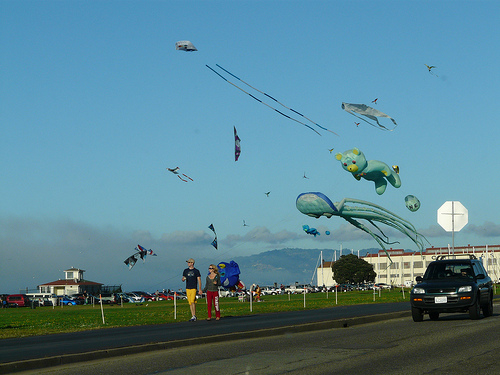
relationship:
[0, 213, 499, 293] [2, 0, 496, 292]
clouds in sky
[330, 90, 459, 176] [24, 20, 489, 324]
kite in sky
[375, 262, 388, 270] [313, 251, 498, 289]
window on building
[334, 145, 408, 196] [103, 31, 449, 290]
kite in sky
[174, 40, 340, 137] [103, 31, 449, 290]
kite in sky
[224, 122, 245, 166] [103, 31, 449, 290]
kite in sky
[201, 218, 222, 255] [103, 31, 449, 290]
kite in sky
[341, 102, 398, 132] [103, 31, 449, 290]
kite in sky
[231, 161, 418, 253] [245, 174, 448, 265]
kite in air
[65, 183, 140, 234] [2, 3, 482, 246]
clouds in sky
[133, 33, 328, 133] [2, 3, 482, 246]
kite in sky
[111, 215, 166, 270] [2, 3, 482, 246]
kite in sky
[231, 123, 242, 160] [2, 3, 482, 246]
kite in sky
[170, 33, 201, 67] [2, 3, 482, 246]
kite in sky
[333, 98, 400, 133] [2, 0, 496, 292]
kite in sky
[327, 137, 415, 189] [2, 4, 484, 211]
kite in sky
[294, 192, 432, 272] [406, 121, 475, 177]
kite in sky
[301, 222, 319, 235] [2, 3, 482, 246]
kite in sky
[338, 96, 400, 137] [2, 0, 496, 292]
kite in sky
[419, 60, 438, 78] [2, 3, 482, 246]
kite in sky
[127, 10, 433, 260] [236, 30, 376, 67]
kite in sky